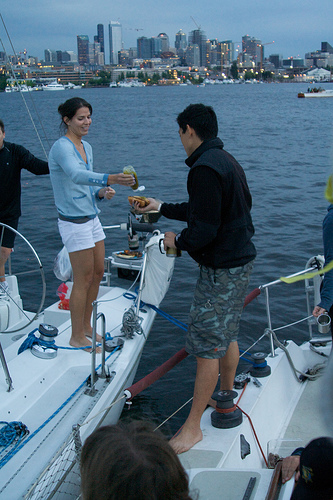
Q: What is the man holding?
A: Hot dog.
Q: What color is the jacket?
A: Black.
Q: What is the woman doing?
A: Putting relish on the hot dog.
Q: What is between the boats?
A: Blue rope.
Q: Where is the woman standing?
A: On a boat.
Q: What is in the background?
A: Cityscape.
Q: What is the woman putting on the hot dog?
A: Relish.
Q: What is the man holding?
A: A hot dog.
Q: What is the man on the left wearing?
A: Black.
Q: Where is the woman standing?
A: On a boat.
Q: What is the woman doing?
A: Pouring something on a hot dog.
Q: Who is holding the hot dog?
A: The man on the right.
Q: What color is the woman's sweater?
A: Blue.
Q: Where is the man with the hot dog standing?
A: On the next boat.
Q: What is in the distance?
A: City skyline.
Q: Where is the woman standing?
A: On a boat.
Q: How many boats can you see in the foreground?
A: Two.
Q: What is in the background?
A: City skyline.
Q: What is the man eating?
A: A hotdog.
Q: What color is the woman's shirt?
A: Blue.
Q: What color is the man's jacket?
A: Black.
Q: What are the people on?
A: Boats.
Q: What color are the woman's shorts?
A: White.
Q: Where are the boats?
A: In the water.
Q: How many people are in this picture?
A: Five.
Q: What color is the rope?
A: Blue.